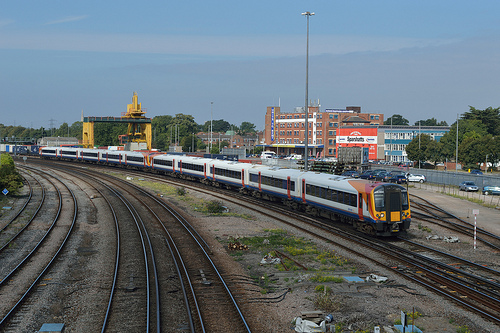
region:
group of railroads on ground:
[10, 150, 242, 332]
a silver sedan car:
[461, 175, 478, 194]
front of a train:
[368, 184, 422, 235]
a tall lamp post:
[291, 3, 324, 173]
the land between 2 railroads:
[239, 222, 323, 322]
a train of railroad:
[7, 138, 419, 236]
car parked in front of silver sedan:
[481, 182, 498, 198]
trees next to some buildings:
[413, 113, 495, 168]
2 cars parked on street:
[460, 177, 499, 199]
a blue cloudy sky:
[14, 18, 282, 95]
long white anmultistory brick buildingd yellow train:
[264, 105, 381, 157]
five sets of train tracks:
[1, 152, 251, 331]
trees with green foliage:
[387, 108, 497, 173]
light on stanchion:
[304, 8, 314, 168]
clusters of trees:
[3, 105, 494, 163]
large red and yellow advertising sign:
[334, 128, 378, 161]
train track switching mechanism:
[110, 263, 417, 303]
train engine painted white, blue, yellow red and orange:
[299, 169, 412, 239]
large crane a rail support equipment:
[81, 92, 154, 148]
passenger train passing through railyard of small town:
[2, 1, 498, 328]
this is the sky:
[53, 56, 128, 99]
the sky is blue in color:
[83, 3, 150, 25]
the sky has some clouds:
[143, 27, 277, 73]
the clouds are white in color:
[140, 40, 219, 50]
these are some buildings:
[258, 105, 439, 165]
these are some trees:
[447, 110, 498, 153]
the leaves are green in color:
[458, 123, 478, 150]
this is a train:
[29, 147, 434, 242]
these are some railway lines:
[6, 196, 223, 326]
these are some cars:
[358, 167, 420, 179]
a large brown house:
[264, 112, 368, 144]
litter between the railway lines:
[270, 275, 419, 327]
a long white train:
[34, 143, 430, 261]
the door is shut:
[354, 192, 363, 209]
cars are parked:
[463, 175, 499, 193]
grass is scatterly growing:
[241, 234, 354, 309]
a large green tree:
[402, 105, 499, 166]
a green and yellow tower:
[58, 108, 165, 146]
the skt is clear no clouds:
[23, 30, 238, 90]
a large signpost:
[303, 3, 309, 173]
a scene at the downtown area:
[2, 6, 496, 316]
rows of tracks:
[1, 155, 281, 331]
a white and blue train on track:
[0, 125, 427, 252]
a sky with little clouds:
[1, 0, 498, 148]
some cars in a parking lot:
[309, 143, 498, 203]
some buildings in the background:
[182, 88, 494, 183]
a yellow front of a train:
[366, 176, 418, 246]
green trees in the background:
[4, 106, 246, 159]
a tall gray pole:
[292, 8, 323, 173]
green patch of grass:
[221, 215, 377, 314]